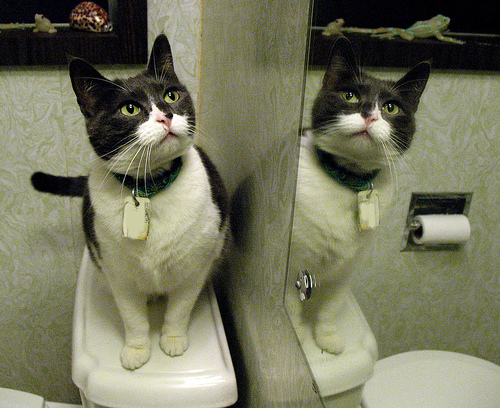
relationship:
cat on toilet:
[70, 68, 233, 265] [78, 327, 229, 402]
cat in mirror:
[70, 68, 233, 265] [329, 32, 452, 242]